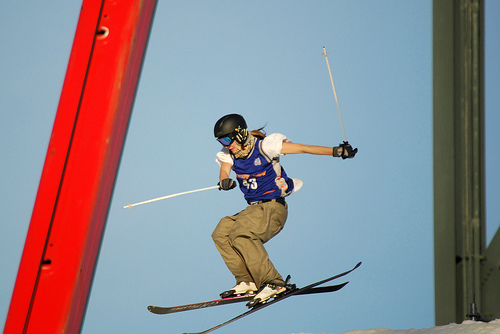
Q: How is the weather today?
A: It is clear.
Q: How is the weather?
A: It is clear.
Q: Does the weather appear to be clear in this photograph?
A: Yes, it is clear.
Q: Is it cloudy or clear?
A: It is clear.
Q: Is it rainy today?
A: No, it is clear.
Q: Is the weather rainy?
A: No, it is clear.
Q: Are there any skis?
A: Yes, there are skis.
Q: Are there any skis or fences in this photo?
A: Yes, there are skis.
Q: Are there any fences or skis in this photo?
A: Yes, there are skis.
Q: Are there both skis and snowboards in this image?
A: No, there are skis but no snowboards.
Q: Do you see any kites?
A: No, there are no kites.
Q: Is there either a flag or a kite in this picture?
A: No, there are no kites or flags.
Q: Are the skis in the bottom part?
A: Yes, the skis are in the bottom of the image.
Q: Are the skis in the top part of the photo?
A: No, the skis are in the bottom of the image.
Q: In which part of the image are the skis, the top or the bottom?
A: The skis are in the bottom of the image.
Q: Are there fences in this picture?
A: No, there are no fences.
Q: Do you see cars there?
A: No, there are no cars.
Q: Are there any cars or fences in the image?
A: No, there are no cars or fences.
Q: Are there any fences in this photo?
A: No, there are no fences.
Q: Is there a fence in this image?
A: No, there are no fences.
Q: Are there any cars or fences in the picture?
A: No, there are no fences or cars.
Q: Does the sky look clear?
A: Yes, the sky is clear.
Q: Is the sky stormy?
A: No, the sky is clear.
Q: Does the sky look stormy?
A: No, the sky is clear.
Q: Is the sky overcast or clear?
A: The sky is clear.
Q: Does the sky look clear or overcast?
A: The sky is clear.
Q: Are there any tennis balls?
A: No, there are no tennis balls.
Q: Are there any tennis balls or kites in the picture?
A: No, there are no tennis balls or kites.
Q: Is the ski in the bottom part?
A: Yes, the ski is in the bottom of the image.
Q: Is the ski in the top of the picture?
A: No, the ski is in the bottom of the image.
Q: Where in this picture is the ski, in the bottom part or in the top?
A: The ski is in the bottom of the image.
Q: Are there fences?
A: No, there are no fences.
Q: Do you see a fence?
A: No, there are no fences.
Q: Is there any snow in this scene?
A: Yes, there is snow.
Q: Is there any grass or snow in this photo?
A: Yes, there is snow.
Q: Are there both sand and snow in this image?
A: No, there is snow but no sand.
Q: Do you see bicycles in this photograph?
A: No, there are no bicycles.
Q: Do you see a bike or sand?
A: No, there are no bikes or sand.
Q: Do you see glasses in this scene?
A: No, there are no glasses.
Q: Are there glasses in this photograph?
A: No, there are no glasses.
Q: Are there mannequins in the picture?
A: No, there are no mannequins.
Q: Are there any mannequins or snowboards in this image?
A: No, there are no mannequins or snowboards.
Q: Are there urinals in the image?
A: No, there are no urinals.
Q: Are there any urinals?
A: No, there are no urinals.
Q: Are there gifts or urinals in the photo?
A: No, there are no urinals or gifts.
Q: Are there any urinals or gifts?
A: No, there are no urinals or gifts.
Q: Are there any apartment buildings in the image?
A: No, there are no apartment buildings.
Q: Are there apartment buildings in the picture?
A: No, there are no apartment buildings.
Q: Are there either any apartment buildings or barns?
A: No, there are no apartment buildings or barns.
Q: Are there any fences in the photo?
A: No, there are no fences.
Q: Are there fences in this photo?
A: No, there are no fences.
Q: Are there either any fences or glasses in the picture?
A: No, there are no fences or glasses.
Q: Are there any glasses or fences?
A: No, there are no fences or glasses.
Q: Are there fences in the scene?
A: No, there are no fences.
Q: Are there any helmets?
A: Yes, there is a helmet.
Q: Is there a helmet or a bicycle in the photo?
A: Yes, there is a helmet.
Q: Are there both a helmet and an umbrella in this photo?
A: No, there is a helmet but no umbrellas.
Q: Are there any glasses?
A: No, there are no glasses.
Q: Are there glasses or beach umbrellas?
A: No, there are no glasses or beach umbrellas.